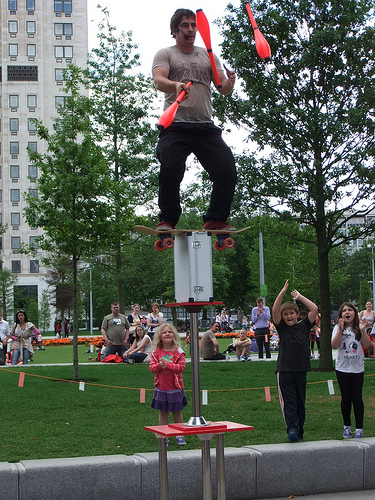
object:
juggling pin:
[244, 1, 271, 64]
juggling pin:
[195, 8, 222, 89]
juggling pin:
[157, 79, 194, 132]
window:
[54, 0, 72, 13]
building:
[0, 0, 90, 332]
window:
[54, 23, 73, 35]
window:
[55, 45, 73, 58]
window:
[55, 69, 73, 81]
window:
[55, 96, 72, 109]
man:
[100, 302, 131, 363]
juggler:
[151, 8, 238, 233]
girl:
[149, 322, 189, 447]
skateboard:
[133, 225, 252, 251]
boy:
[272, 279, 319, 441]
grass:
[0, 329, 375, 462]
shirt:
[272, 315, 317, 375]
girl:
[330, 301, 371, 439]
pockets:
[106, 343, 127, 350]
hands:
[107, 340, 127, 347]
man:
[251, 297, 271, 358]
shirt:
[251, 305, 271, 328]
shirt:
[155, 347, 176, 391]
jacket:
[148, 345, 186, 390]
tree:
[72, 0, 161, 315]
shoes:
[156, 219, 237, 231]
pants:
[156, 122, 238, 226]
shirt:
[152, 45, 224, 124]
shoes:
[287, 429, 303, 442]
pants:
[276, 371, 307, 439]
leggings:
[336, 369, 365, 428]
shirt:
[331, 323, 365, 373]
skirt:
[150, 387, 188, 413]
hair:
[151, 322, 182, 353]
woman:
[121, 325, 153, 365]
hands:
[281, 279, 301, 300]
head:
[280, 301, 300, 327]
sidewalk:
[0, 349, 374, 370]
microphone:
[174, 27, 188, 40]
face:
[176, 16, 197, 45]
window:
[26, 0, 35, 12]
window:
[26, 20, 36, 33]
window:
[27, 44, 36, 57]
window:
[27, 95, 37, 108]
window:
[28, 142, 37, 154]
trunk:
[71, 98, 79, 379]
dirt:
[52, 378, 98, 384]